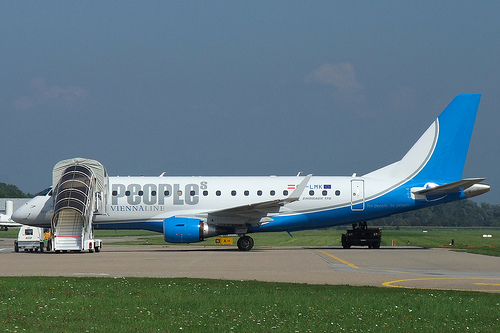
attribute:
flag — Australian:
[285, 179, 300, 191]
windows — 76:
[107, 186, 352, 198]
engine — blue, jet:
[158, 211, 198, 247]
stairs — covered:
[55, 165, 92, 216]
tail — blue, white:
[391, 87, 483, 181]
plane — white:
[12, 75, 490, 247]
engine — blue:
[160, 211, 205, 239]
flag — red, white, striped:
[284, 181, 299, 193]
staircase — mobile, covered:
[50, 169, 102, 252]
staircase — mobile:
[45, 146, 110, 270]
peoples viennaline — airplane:
[108, 176, 215, 216]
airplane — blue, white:
[2, 92, 489, 254]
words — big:
[113, 181, 218, 211]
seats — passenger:
[112, 185, 249, 200]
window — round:
[135, 187, 145, 197]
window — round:
[161, 187, 172, 197]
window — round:
[203, 190, 211, 197]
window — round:
[229, 188, 239, 198]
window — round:
[255, 185, 265, 201]